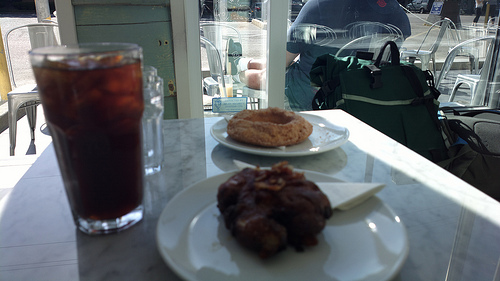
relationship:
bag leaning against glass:
[308, 41, 450, 164] [290, 5, 490, 107]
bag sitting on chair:
[308, 50, 443, 155] [336, 28, 489, 105]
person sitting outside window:
[290, 0, 438, 102] [290, 2, 485, 108]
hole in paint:
[165, 79, 177, 94] [80, 5, 178, 115]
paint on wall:
[80, 5, 178, 115] [58, 0, 199, 119]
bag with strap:
[308, 41, 450, 164] [419, 73, 437, 103]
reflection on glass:
[287, 21, 409, 62] [283, 0, 498, 110]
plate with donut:
[211, 112, 348, 157] [226, 106, 313, 147]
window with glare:
[289, 4, 499, 114] [286, 17, 409, 54]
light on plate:
[190, 222, 216, 270] [151, 159, 417, 279]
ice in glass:
[49, 48, 129, 89] [29, 40, 144, 234]